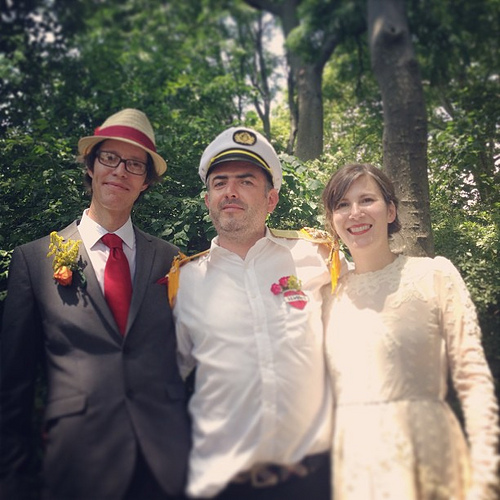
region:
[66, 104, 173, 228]
The man is smiling.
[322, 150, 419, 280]
The woman is smiling.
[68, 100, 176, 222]
The man is wearing a hat.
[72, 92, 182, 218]
The hat has a red band.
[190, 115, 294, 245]
The man is wearing a hat.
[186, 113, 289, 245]
The man is smiling.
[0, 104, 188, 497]
The man is wearing a suit jacket.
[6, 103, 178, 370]
The man is wearing a tie.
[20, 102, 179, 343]
The man's tie is red.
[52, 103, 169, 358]
The man is wearing a white shirt.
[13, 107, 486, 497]
three people side by side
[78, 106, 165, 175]
straw hat with red band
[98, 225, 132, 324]
red tie under white collar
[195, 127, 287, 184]
captains hat with gold embelm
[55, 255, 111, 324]
red flower on lapel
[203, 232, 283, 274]
open collar of shirt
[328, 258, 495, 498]
lace dress with long sleeves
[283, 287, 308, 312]
red heart with white ribbon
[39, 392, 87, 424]
gray cover on pocket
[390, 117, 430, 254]
bark on tree truck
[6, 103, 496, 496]
Three people posing for a photograph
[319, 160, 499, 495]
Smiling bride in a white dress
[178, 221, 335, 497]
White button down shirt with epaulets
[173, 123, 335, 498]
Man in a with a captains hat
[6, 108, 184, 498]
Tall man in a grey suit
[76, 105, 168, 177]
Straw hat with a red band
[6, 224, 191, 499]
Grey suit worn with a red tie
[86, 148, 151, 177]
Black rimmed glasses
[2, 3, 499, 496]
Bride and groom posing with the captain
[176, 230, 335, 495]
Partially untucked white shirt with heart on pocket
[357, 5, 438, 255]
a large gray tree branch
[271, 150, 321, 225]
green tree leaves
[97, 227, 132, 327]
a man's red tie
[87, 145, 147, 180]
a man's eyeglasses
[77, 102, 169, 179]
a brown and red hat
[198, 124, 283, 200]
a man's white cap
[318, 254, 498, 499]
part of a woman's long sleeve white dress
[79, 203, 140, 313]
part of a man's collared white shirt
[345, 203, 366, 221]
the nose of a woman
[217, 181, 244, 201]
the nose of a man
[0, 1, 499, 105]
a bunch of green trees.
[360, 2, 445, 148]
a tree stem.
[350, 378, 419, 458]
a woman is wearing a beige dress.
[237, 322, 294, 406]
a man is wearing a white shirt.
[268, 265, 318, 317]
a man has a rose and flowers on his white shirt.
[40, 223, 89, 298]
a man is wearing a rose on his jacket.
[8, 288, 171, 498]
a man is wearing a grey jacket.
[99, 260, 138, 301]
a man is wearing a burgundy tie.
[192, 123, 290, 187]
a man is wearing a white and black hat.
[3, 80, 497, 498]
three people are smiling and happy.